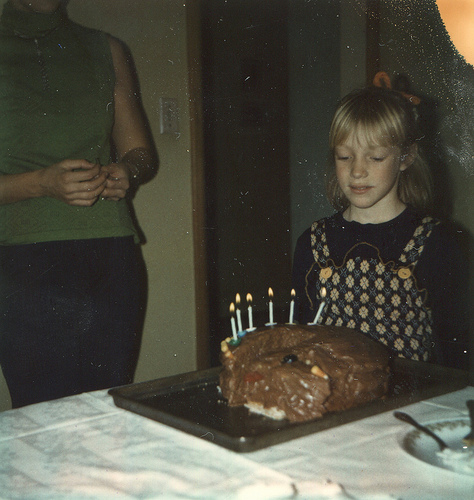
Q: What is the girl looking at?
A: A cake.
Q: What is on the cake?
A: Six candles.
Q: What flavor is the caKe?
A: Chocolate.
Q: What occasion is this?
A: Birthday.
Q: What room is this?
A: Kitchen.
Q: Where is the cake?
A: Table.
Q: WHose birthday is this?
A: Little girl.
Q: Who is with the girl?
A: Family.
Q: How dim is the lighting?
A: Very dim.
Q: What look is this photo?
A: Antique.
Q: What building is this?
A: House.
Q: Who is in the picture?
A: A girl.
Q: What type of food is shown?
A: Birthday cake.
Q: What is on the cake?
A: Blue candles.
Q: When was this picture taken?
A: A birthday party.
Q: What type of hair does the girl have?
A: Blonde.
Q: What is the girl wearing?
A: Argyle dress.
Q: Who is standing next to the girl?
A: A woman.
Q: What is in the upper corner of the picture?
A: Orange balloon.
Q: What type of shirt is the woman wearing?
A: Sleeveless green.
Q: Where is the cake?
A: On a pan.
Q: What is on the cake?
A: Candles.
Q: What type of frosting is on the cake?
A: Chocolate.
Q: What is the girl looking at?
A: A birthday cake.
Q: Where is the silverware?
A: On a plate to the right of the cake.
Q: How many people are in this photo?
A: Two.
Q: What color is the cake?
A: Brown.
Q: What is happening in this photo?
A: A birthday.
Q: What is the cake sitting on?
A: A metal baking tray.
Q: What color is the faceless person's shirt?
A: Green.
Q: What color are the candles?
A: White.